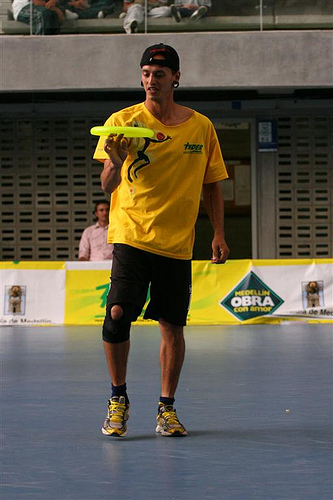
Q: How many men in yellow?
A: One.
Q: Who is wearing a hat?
A: Man in yellow.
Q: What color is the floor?
A: Blue.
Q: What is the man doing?
A: Looking at frisbee.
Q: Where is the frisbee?
A: His right hand.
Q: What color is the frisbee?
A: Yellow.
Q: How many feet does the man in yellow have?
A: Two.